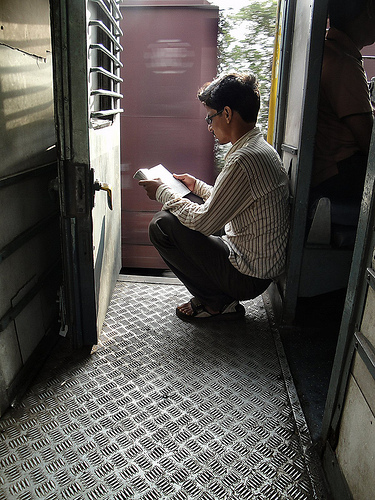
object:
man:
[133, 57, 293, 335]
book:
[133, 164, 190, 204]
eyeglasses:
[198, 108, 224, 129]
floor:
[27, 258, 316, 499]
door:
[42, 0, 147, 354]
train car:
[8, 4, 374, 496]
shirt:
[154, 126, 301, 284]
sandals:
[175, 294, 255, 328]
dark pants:
[138, 210, 270, 301]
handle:
[90, 167, 120, 218]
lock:
[43, 152, 120, 219]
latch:
[46, 147, 98, 226]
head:
[196, 59, 260, 146]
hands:
[141, 179, 160, 201]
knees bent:
[125, 205, 220, 285]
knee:
[148, 202, 186, 252]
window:
[85, 1, 126, 128]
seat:
[151, 283, 305, 346]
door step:
[97, 265, 266, 335]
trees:
[217, 8, 278, 85]